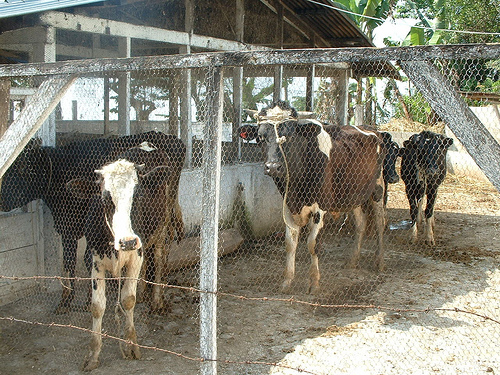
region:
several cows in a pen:
[0, 67, 455, 372]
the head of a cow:
[85, 155, 146, 260]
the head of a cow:
[252, 110, 294, 180]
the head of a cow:
[417, 131, 443, 181]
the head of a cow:
[381, 141, 401, 187]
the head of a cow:
[0, 138, 53, 209]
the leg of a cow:
[82, 263, 109, 370]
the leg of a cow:
[118, 273, 140, 365]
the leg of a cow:
[278, 223, 298, 297]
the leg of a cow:
[301, 230, 325, 297]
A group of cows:
[0, 135, 462, 367]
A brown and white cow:
[59, 143, 176, 373]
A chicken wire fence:
[1, 50, 491, 370]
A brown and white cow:
[235, 108, 390, 294]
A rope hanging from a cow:
[257, 110, 307, 240]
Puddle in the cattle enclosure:
[388, 213, 418, 236]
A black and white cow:
[400, 130, 453, 250]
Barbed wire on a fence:
[1, 271, 498, 366]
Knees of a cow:
[85, 294, 140, 316]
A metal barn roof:
[282, 0, 402, 78]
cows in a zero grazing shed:
[52, 67, 468, 349]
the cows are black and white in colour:
[14, 111, 446, 355]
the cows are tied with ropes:
[251, 67, 412, 354]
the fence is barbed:
[5, 53, 471, 373]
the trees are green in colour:
[363, 0, 478, 37]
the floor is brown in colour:
[286, 298, 457, 367]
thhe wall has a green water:
[226, 171, 253, 227]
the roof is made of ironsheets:
[308, 13, 365, 48]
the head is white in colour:
[83, 170, 148, 245]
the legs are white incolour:
[275, 215, 329, 282]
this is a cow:
[241, 92, 394, 270]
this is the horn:
[299, 102, 328, 125]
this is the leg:
[304, 204, 329, 297]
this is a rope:
[283, 125, 293, 246]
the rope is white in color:
[274, 169, 291, 234]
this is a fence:
[243, 82, 422, 371]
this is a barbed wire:
[266, 291, 369, 309]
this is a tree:
[412, 8, 497, 28]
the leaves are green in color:
[445, 11, 496, 26]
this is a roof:
[298, 12, 363, 41]